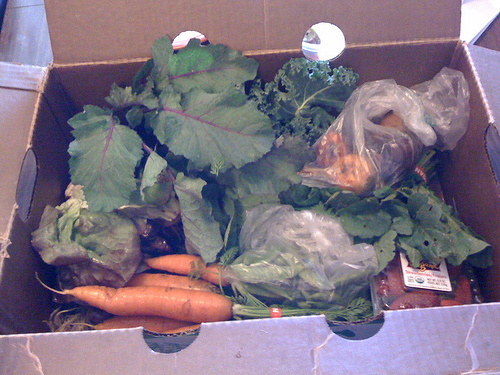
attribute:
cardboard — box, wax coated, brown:
[2, 2, 500, 375]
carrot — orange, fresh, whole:
[35, 270, 377, 333]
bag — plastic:
[237, 202, 380, 308]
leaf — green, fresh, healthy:
[66, 103, 149, 211]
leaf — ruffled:
[397, 189, 493, 280]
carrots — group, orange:
[35, 247, 372, 333]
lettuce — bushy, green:
[254, 54, 357, 142]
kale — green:
[337, 190, 390, 244]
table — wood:
[1, 1, 500, 226]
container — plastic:
[367, 258, 483, 313]